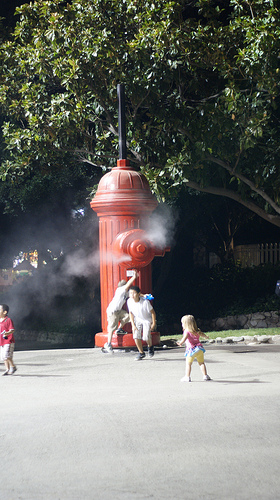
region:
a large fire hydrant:
[61, 101, 213, 363]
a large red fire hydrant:
[69, 143, 201, 378]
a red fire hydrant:
[48, 139, 184, 357]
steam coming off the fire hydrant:
[51, 210, 202, 406]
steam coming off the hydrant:
[68, 146, 193, 348]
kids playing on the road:
[53, 264, 267, 400]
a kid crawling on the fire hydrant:
[59, 214, 208, 364]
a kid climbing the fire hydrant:
[92, 262, 228, 351]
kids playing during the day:
[79, 235, 268, 423]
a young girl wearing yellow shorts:
[168, 292, 238, 413]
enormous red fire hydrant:
[83, 163, 168, 352]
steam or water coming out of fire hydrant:
[93, 212, 175, 272]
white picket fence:
[228, 240, 278, 265]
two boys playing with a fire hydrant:
[85, 275, 161, 355]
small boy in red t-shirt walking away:
[0, 301, 27, 375]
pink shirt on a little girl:
[181, 332, 203, 356]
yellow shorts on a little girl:
[183, 344, 207, 364]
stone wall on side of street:
[211, 307, 266, 342]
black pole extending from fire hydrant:
[105, 94, 142, 162]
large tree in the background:
[156, 143, 279, 225]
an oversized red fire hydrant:
[85, 163, 169, 347]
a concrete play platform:
[28, 402, 226, 488]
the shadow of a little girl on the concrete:
[220, 370, 268, 390]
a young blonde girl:
[174, 314, 215, 386]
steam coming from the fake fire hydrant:
[34, 215, 184, 276]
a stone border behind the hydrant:
[209, 312, 273, 324]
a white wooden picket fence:
[210, 242, 274, 273]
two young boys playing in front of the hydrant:
[100, 275, 158, 362]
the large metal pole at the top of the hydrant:
[111, 86, 128, 165]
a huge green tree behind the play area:
[149, 118, 278, 227]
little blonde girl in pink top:
[176, 314, 212, 381]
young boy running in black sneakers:
[126, 285, 155, 361]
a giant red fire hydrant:
[90, 158, 172, 348]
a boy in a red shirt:
[0, 302, 16, 374]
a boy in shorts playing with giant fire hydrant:
[103, 271, 138, 353]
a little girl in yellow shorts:
[175, 314, 208, 380]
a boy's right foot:
[134, 350, 145, 360]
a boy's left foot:
[146, 344, 154, 356]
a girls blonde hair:
[181, 314, 198, 331]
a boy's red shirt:
[0, 316, 12, 345]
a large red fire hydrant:
[89, 158, 168, 346]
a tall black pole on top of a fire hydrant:
[116, 83, 128, 158]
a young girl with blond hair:
[176, 314, 211, 382]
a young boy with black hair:
[126, 286, 155, 359]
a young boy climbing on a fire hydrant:
[101, 271, 141, 351]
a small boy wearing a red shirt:
[0, 303, 16, 375]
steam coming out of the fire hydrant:
[1, 203, 173, 323]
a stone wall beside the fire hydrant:
[204, 310, 277, 328]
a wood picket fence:
[235, 242, 278, 266]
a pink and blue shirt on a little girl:
[183, 330, 205, 354]